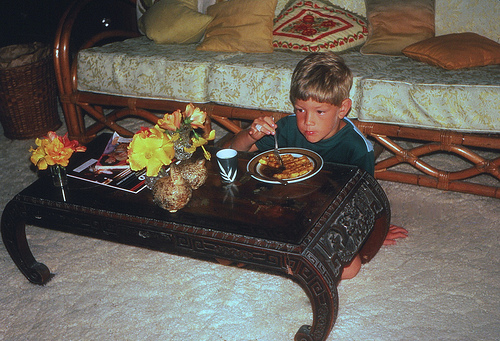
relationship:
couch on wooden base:
[61, 0, 498, 199] [55, 81, 498, 202]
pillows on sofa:
[401, 32, 498, 67] [50, 0, 497, 188]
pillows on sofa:
[358, 0, 435, 50] [50, 0, 497, 188]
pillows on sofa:
[273, 2, 368, 55] [50, 0, 497, 188]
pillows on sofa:
[201, 0, 277, 50] [50, 0, 497, 188]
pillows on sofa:
[136, 4, 213, 42] [50, 0, 497, 188]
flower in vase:
[177, 100, 214, 144] [155, 141, 200, 171]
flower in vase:
[152, 109, 186, 135] [155, 141, 200, 171]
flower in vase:
[123, 131, 182, 190] [155, 141, 200, 171]